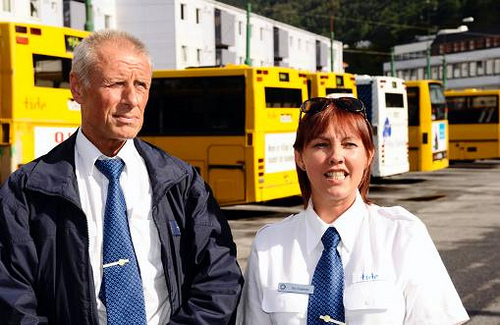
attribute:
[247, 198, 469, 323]
shirt — white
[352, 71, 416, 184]
bus — white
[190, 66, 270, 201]
bus — white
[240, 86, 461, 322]
person — wearing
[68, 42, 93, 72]
hair — gray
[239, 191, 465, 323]
shirt — white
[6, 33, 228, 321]
man — light skinned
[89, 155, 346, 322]
ties — blue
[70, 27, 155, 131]
hair — short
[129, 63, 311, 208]
bus — yellow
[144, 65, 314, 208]
bus — yellow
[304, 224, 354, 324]
tie — blue